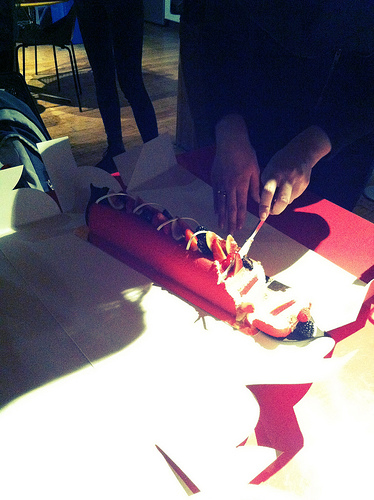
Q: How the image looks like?
A: Good.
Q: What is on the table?
A: Cake.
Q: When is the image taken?
A: When cutting the cake.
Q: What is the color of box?
A: White.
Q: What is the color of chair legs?
A: Black.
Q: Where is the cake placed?
A: On the table.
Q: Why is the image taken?
A: Remembrance.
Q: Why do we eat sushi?
A: Energy.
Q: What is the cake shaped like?
A: A cylinder.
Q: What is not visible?
A: People's heads.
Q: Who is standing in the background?
A: A person.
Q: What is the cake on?
A: Top of a box.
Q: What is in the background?
A: A chair.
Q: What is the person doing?
A: Cutting.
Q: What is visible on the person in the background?
A: Legs.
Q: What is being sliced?
A: Cake.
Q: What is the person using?
A: A knife.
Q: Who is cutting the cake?
A: A person.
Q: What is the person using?
A: A knife.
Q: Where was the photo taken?
A: Inside a room.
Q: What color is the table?
A: Red.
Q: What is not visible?
A: People's faces.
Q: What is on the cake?
A: Fruit.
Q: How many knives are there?
A: One.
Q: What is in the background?
A: Chairs.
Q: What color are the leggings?
A: Black.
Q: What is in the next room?
A: A chair.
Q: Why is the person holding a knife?
A: To cut the food.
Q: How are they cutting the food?
A: In pieces.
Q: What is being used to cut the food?
A: A knife.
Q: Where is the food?
A: On the table.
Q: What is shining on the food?
A: A light.